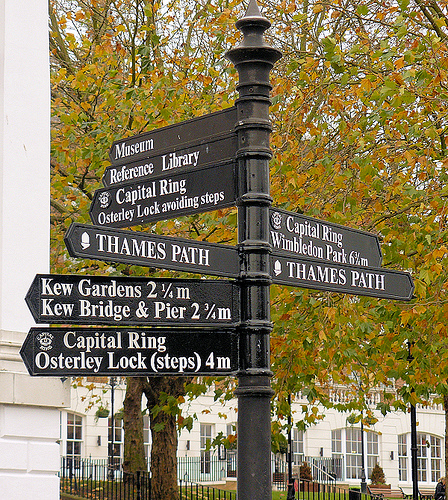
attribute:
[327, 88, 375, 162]
leaves — green, yellow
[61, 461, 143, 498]
gate — black, metal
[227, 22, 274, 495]
pole — black, tall, skinny, pointy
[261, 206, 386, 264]
sign — black, white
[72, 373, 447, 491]
building — white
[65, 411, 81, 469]
window — large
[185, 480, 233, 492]
grass — green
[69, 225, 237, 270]
sign — black, white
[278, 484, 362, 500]
fence — black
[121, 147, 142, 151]
lettering — white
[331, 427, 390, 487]
window — large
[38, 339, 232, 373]
sign — black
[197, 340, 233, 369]
number — 4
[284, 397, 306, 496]
post — black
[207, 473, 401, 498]
area — garden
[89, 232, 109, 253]
letter — t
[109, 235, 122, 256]
letter — h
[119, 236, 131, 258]
letter — a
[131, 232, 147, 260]
letter — m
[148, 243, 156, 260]
letter — e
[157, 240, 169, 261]
letter — s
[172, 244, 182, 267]
letter — p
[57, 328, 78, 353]
letter — c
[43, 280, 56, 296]
letter — k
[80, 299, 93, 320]
letter — b